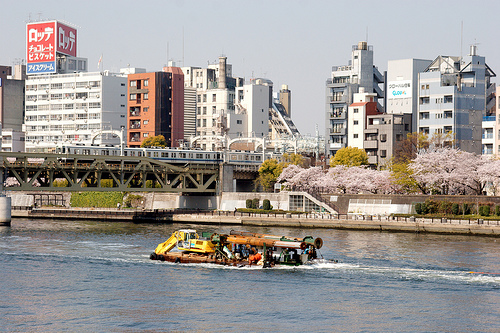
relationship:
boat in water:
[142, 225, 329, 278] [147, 204, 371, 283]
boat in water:
[142, 225, 329, 278] [17, 210, 492, 331]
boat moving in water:
[142, 225, 329, 278] [22, 250, 147, 325]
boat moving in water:
[142, 225, 329, 278] [379, 225, 460, 327]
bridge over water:
[0, 148, 267, 195] [50, 272, 148, 331]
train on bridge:
[59, 143, 276, 161] [8, 153, 281, 211]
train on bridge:
[59, 143, 276, 161] [0, 147, 263, 189]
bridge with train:
[0, 148, 267, 195] [61, 143, 312, 164]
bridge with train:
[0, 148, 267, 195] [52, 143, 274, 171]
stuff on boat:
[155, 231, 268, 251] [159, 249, 280, 269]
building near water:
[359, 109, 414, 169] [50, 276, 478, 326]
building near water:
[7, 64, 139, 176] [35, 248, 183, 331]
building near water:
[7, 64, 139, 176] [17, 210, 492, 331]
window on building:
[76, 81, 87, 88] [24, 70, 126, 162]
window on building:
[88, 79, 102, 86] [414, 51, 486, 162]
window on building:
[89, 91, 103, 97] [20, 74, 125, 149]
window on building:
[87, 79, 100, 88] [20, 74, 125, 149]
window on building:
[85, 101, 99, 108] [20, 74, 125, 149]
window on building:
[61, 112, 76, 121] [20, 74, 125, 149]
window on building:
[50, 113, 60, 122] [20, 74, 125, 149]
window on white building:
[414, 91, 434, 109] [338, 82, 398, 167]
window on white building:
[137, 75, 155, 90] [338, 82, 398, 167]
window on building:
[480, 125, 494, 142] [7, 64, 139, 176]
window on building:
[127, 115, 144, 133] [7, 64, 139, 176]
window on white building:
[331, 72, 349, 87] [191, 75, 272, 149]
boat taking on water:
[142, 225, 329, 278] [17, 210, 492, 331]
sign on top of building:
[26, 20, 78, 72] [23, 19, 129, 156]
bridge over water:
[0, 148, 267, 195] [17, 210, 492, 331]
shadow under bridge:
[174, 193, 219, 212] [15, 139, 295, 204]